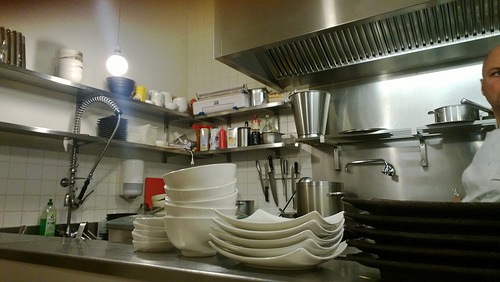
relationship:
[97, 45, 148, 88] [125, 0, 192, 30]
light on ceiling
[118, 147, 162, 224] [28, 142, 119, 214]
dispenser on wall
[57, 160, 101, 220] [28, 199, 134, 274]
faucet over sink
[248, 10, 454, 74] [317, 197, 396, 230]
vent over stove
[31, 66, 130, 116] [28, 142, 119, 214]
shelves on wall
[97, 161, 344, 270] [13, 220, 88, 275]
dishes on counter